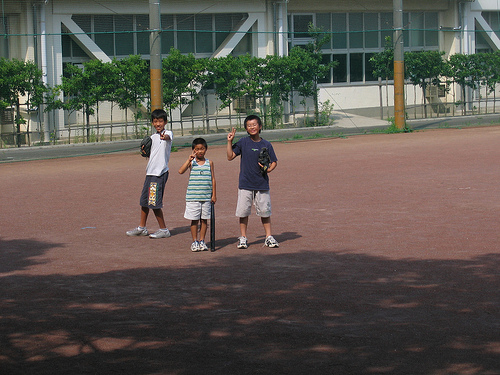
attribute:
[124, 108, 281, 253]
boys — together, standing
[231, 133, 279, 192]
shirt — blue, navy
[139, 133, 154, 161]
mitt — black, dark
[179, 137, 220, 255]
boy — small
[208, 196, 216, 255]
bat — dark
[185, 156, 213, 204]
shirt — tank top, striped, sleeveless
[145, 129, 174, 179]
shirt — white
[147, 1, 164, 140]
pole — two-tone, gold, gray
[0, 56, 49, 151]
tree — green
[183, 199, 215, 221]
shorts — white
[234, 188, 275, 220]
shorts — gray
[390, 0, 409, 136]
pole — gold, gray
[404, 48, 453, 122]
tree — small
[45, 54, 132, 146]
tree — green